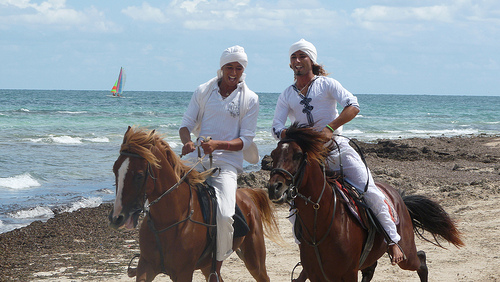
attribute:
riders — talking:
[206, 36, 357, 177]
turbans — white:
[218, 39, 320, 60]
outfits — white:
[189, 93, 347, 128]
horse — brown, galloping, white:
[109, 140, 209, 281]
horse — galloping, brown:
[274, 136, 364, 281]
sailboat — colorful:
[113, 66, 133, 99]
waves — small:
[37, 130, 97, 147]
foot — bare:
[392, 242, 403, 263]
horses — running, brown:
[121, 135, 341, 234]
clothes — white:
[201, 95, 253, 136]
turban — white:
[292, 40, 317, 52]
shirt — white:
[201, 81, 258, 149]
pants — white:
[216, 164, 239, 241]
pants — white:
[338, 148, 374, 181]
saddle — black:
[199, 188, 218, 226]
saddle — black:
[347, 196, 373, 224]